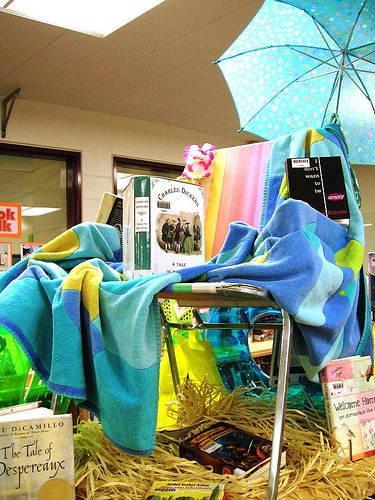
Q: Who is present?
A: No one.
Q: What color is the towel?
A: Blue.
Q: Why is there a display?
A: Attraction.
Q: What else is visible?
A: Chair.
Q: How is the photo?
A: Clear.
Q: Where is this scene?
A: At a book store.